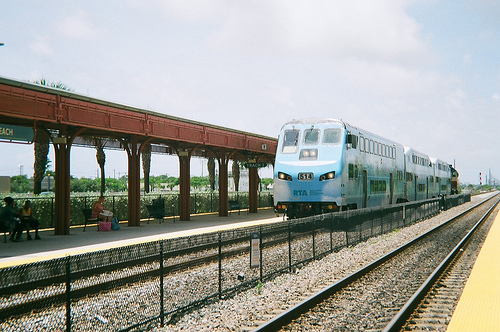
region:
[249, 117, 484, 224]
light blue train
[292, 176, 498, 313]
railroad track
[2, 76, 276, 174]
rust colored bridge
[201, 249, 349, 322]
gray colored gravel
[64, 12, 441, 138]
clouds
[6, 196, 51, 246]
two people sitting on a bench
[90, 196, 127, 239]
woman in an orange shirt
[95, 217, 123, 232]
pink bag on the ground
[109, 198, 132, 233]
blue bag on the ground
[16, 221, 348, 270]
metal chain link fence with a sign attached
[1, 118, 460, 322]
light blue train on a track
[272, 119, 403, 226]
engine of light blue train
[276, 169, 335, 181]
headlights of light blue train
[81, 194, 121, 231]
person with luggage sitting on a bench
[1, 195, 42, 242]
people sitting on a bench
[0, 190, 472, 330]
black fence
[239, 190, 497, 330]
train track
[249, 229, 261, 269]
sign on fence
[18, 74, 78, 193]
tree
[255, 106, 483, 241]
the train is blue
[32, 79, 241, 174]
the tracks are red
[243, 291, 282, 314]
the ground has rocks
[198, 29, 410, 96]
the sky is clear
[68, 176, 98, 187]
the trees are green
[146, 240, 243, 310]
the fence is black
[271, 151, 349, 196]
the train has lights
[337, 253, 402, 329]
the tracks go straight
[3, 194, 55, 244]
people are sitting down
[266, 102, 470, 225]
the train is long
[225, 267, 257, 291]
large gray stone on ground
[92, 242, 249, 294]
large wire mesh fence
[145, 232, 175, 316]
black post in fence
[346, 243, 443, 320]
long silver train tracks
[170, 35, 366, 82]
white clouds in the sky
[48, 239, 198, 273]
sunlight on the platform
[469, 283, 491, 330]
yellow paint on platform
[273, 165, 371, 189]
yellow lights on train front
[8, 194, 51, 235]
people sitting on bench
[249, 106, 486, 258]
blue and white train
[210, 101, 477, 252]
train entering into station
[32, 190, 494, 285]
fencing between separate tracks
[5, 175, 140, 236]
people seated on platform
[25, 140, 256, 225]
support beams for roofing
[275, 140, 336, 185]
sets of lights on front of train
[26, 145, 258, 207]
tree trunks on other side of station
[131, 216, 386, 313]
grey gravel lining tracks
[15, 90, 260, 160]
repeated design on edge of roof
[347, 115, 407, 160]
windows high on train car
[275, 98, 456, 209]
light blue train with white highlights